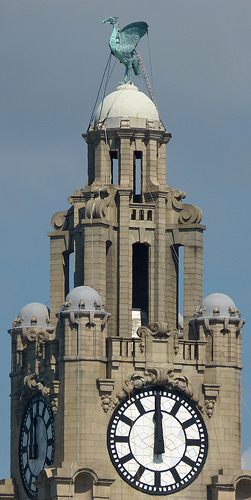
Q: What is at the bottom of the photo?
A: A clock.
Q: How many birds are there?
A: One.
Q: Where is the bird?
A: On top of the building.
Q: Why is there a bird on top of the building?
A: For decoration.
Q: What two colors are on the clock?
A: White and black.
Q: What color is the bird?
A: Blue.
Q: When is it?
A: Noon.